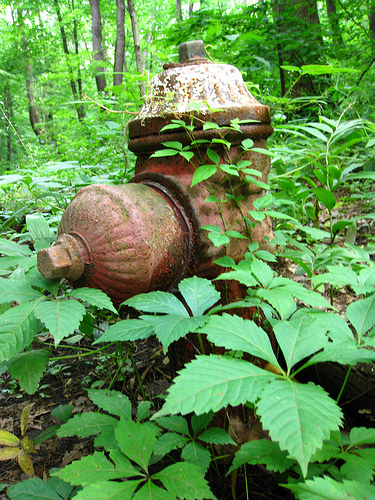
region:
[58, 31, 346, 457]
an old fire hydrant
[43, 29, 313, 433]
a red and white fire hydrant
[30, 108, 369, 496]
plants all around fire hydrant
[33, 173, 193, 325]
one valve on fire hydrant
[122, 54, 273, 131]
chipping white pant on hydrant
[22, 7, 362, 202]
trees behind the fire hyrdrant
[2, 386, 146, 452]
dead leaves on the ground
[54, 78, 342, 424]
plants almost covering hydrant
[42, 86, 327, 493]
plants beginning to hide hydrant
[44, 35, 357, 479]
a fire hydrant in the woods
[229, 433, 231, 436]
part of a root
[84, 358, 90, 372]
part of a surface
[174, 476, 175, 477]
part of a branch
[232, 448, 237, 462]
part of a grass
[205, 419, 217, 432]
edge of a grass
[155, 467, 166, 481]
part of a root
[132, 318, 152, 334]
edge of a pole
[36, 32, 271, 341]
fire hydrant in the woods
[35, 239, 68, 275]
bolt on the hydrant's cap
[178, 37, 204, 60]
bolt on the top of the fire hydrant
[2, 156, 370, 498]
weeds growing around the fire hydrant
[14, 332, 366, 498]
ground around the fire hydrant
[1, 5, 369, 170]
trees in the forest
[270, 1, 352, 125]
large brown tree trunk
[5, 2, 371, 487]
forest the fire hydrant is in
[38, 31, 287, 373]
decrepit old fire hydrant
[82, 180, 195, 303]
green moss growing on fire hydrant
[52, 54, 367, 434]
the hydant is rusted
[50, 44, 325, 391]
the hydrant is red brown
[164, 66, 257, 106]
white stuff is on the hydrant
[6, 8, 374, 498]
the photo was taken in the forest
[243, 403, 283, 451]
the edge of leat is saw edged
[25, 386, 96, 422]
dead leaves are on the ground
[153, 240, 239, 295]
the hydrant is wet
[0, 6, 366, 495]
the vegetation is ver green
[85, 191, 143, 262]
soil is on the hydrant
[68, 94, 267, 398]
hydrant in thick grass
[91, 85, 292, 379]
red and rusty hydrant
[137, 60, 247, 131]
top of plug is grey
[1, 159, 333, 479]
green weeds around plug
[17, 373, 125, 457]
brown dirt on ground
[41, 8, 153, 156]
grey trunks of trees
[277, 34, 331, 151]
large brown tree trunk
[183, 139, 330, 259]
weeds growing on ground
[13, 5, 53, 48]
light shining through trees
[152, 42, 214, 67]
grey cap on plug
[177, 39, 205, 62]
Dark grey square on a hydrant top.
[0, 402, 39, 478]
Yellow green leaves on the ground.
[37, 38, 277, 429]
An old worn fire hydrant.